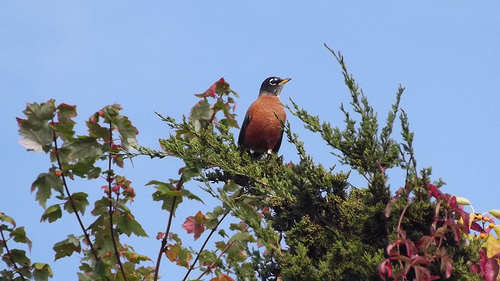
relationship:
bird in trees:
[253, 71, 295, 102] [151, 43, 497, 280]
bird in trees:
[227, 76, 295, 162] [151, 43, 497, 280]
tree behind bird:
[20, 108, 188, 270] [227, 76, 295, 162]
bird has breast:
[253, 71, 295, 102] [268, 98, 278, 108]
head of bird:
[259, 72, 290, 95] [227, 76, 295, 162]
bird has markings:
[227, 76, 295, 162] [271, 79, 272, 81]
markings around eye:
[271, 79, 272, 81] [271, 80, 277, 84]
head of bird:
[259, 72, 290, 95] [253, 71, 295, 102]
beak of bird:
[277, 75, 292, 88] [253, 71, 295, 102]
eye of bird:
[271, 80, 277, 84] [253, 71, 295, 102]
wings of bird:
[236, 110, 254, 150] [253, 71, 295, 102]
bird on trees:
[253, 71, 295, 102] [151, 43, 497, 280]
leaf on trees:
[74, 141, 105, 178] [151, 43, 497, 280]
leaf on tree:
[74, 141, 105, 178] [20, 108, 188, 270]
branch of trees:
[152, 182, 194, 280] [151, 43, 497, 280]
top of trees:
[178, 142, 419, 155] [151, 43, 497, 280]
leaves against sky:
[28, 100, 72, 147] [12, 15, 47, 37]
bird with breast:
[253, 71, 295, 102] [268, 98, 278, 108]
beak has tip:
[277, 75, 292, 88] [289, 79, 291, 80]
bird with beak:
[253, 71, 295, 102] [277, 75, 292, 88]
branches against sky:
[211, 205, 239, 259] [12, 15, 47, 37]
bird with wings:
[253, 71, 295, 102] [240, 130, 283, 156]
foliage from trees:
[393, 243, 490, 280] [14, 238, 497, 280]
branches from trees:
[211, 205, 239, 259] [151, 43, 497, 280]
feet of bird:
[249, 154, 273, 161] [253, 71, 295, 102]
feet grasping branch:
[249, 154, 273, 161] [229, 156, 294, 191]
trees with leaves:
[151, 43, 497, 280] [28, 100, 72, 147]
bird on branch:
[253, 71, 295, 102] [229, 156, 294, 191]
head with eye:
[259, 72, 290, 95] [271, 80, 277, 84]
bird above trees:
[253, 71, 295, 102] [14, 238, 497, 280]